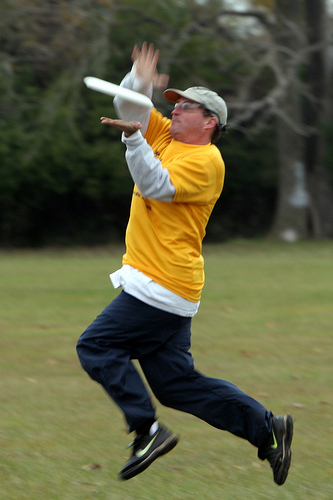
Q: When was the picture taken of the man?
A: Daytime.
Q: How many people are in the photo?
A: One.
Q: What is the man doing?
A: Playing Frisbee.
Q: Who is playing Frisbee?
A: A man.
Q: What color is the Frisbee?
A: White.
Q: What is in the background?
A: Trees.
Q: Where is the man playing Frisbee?
A: The park.